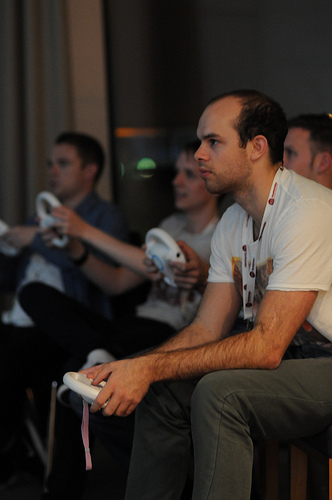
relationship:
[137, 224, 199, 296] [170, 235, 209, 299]
controller in hand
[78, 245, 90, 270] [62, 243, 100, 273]
black watch worn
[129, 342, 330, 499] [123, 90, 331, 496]
gray pants man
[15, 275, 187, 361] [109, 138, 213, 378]
black pants man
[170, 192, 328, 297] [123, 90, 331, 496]
white shirt man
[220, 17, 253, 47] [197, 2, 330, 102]
gray interior wall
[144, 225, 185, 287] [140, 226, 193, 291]
wii steering wheel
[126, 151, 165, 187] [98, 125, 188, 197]
light in background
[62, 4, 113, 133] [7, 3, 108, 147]
thick tan curtain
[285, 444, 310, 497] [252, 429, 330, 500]
legs wooden chair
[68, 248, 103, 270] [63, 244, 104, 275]
band on wrist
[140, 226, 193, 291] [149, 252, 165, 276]
wheel blue circle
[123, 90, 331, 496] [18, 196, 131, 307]
man blue shirt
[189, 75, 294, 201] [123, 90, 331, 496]
head of man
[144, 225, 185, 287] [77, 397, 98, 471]
wii wheel cord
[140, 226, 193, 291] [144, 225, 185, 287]
wheel for wii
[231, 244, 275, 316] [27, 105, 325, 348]
tag for competition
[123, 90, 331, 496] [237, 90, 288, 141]
man dark hair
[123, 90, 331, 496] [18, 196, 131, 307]
man wearing shirt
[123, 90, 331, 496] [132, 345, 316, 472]
man wearing jeans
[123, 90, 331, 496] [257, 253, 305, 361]
man on arm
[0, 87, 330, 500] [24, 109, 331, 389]
four people playin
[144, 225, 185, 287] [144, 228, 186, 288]
wii driving controller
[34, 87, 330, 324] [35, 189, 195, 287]
four people racing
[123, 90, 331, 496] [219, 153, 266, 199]
man to shave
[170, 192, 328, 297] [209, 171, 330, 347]
white t shirt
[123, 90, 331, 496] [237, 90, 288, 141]
man receeding hair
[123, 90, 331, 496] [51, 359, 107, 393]
man playing game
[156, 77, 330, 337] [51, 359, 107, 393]
person playing game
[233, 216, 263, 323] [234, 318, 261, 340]
lanyard admission ticket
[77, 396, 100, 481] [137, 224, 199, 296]
string on controller